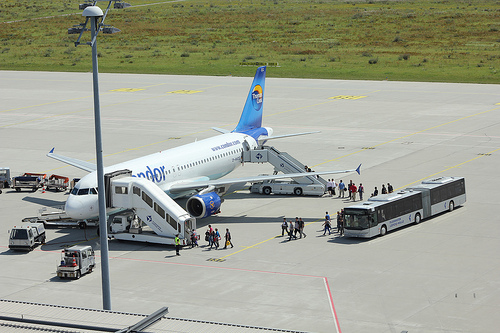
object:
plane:
[45, 64, 363, 249]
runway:
[5, 71, 498, 332]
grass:
[2, 0, 496, 78]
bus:
[340, 174, 468, 240]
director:
[172, 233, 184, 256]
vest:
[173, 237, 181, 245]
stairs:
[129, 177, 199, 247]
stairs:
[251, 144, 334, 192]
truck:
[55, 242, 98, 280]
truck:
[7, 221, 47, 252]